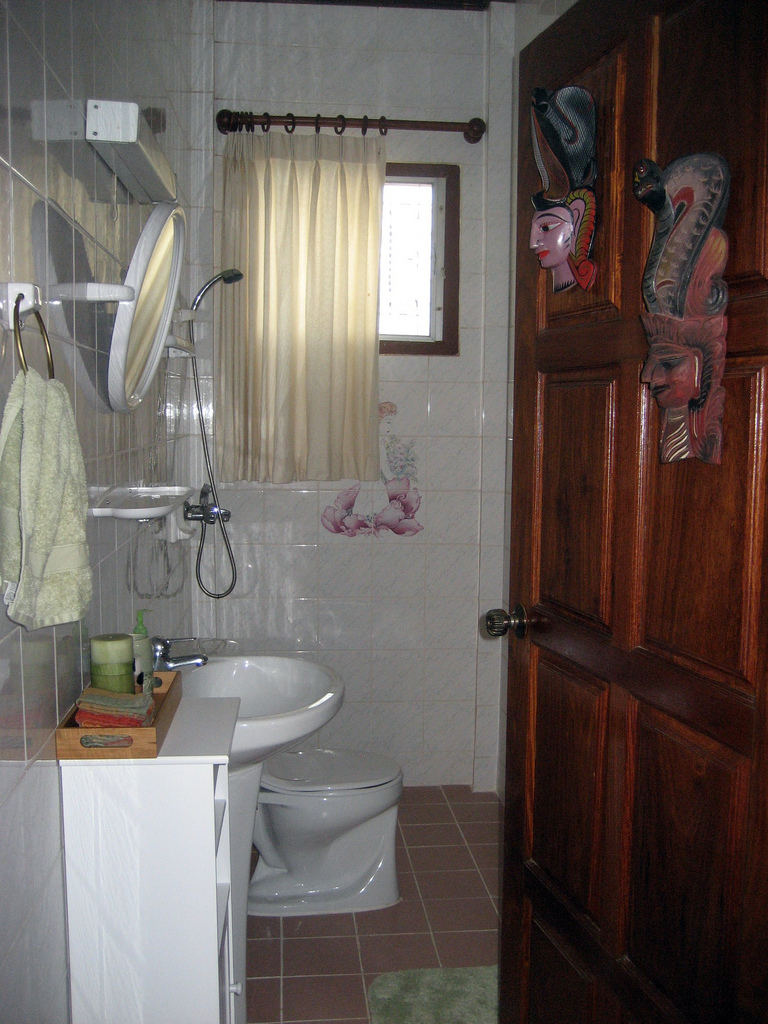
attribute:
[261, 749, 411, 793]
toilet lid — white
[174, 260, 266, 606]
shower head — flexible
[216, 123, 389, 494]
curtain panel — light tan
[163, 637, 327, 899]
bathroom sink — white, porcelain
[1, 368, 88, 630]
towel — white, fluffy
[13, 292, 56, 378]
towel ring — gold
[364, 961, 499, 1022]
bath mat — pale, green